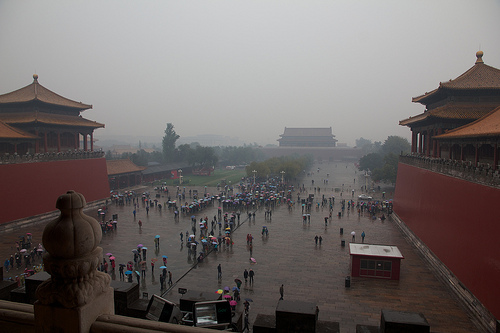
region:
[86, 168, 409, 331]
a group of people standing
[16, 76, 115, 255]
a long home in road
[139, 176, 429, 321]
a number of people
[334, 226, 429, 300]
a small room in road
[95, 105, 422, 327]
a beautiful view of people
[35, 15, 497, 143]
a beautiful view of sky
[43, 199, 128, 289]
top part of the wall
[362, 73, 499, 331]
a part of the large building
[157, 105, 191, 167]
a very long tree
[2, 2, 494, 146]
gray and foggy sky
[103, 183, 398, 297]
groups of people gathered in the square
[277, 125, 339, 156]
furthest building in the distance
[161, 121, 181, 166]
tallest tree, just left of center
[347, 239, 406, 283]
random red building in the square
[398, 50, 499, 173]
building on the right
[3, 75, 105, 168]
tallest building on the left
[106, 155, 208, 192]
short small building on left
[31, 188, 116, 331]
decorative piece of stone railing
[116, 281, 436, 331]
black boxes on ground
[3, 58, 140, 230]
red and brown building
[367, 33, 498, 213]
red and brown building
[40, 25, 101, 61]
white clouds in blue sky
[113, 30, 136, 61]
white clouds in blue sky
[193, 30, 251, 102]
white clouds in blue sky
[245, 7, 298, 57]
white clouds in blue sky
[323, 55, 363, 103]
white clouds in blue sky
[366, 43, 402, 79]
white clouds in blue sky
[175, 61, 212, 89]
white clouds in blue sky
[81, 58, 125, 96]
white clouds in blue sky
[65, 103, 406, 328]
people that are walking outside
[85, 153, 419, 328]
people that are walking in the rain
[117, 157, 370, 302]
people walking outside in the rain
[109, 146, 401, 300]
people holding umbrellas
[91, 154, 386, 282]
people standing in the rain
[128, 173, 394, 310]
people holding open umbrellas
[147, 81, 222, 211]
a tree in the distance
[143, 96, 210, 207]
a tree with green leaves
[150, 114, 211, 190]
green leaves on a tree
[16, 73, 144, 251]
the top of a building